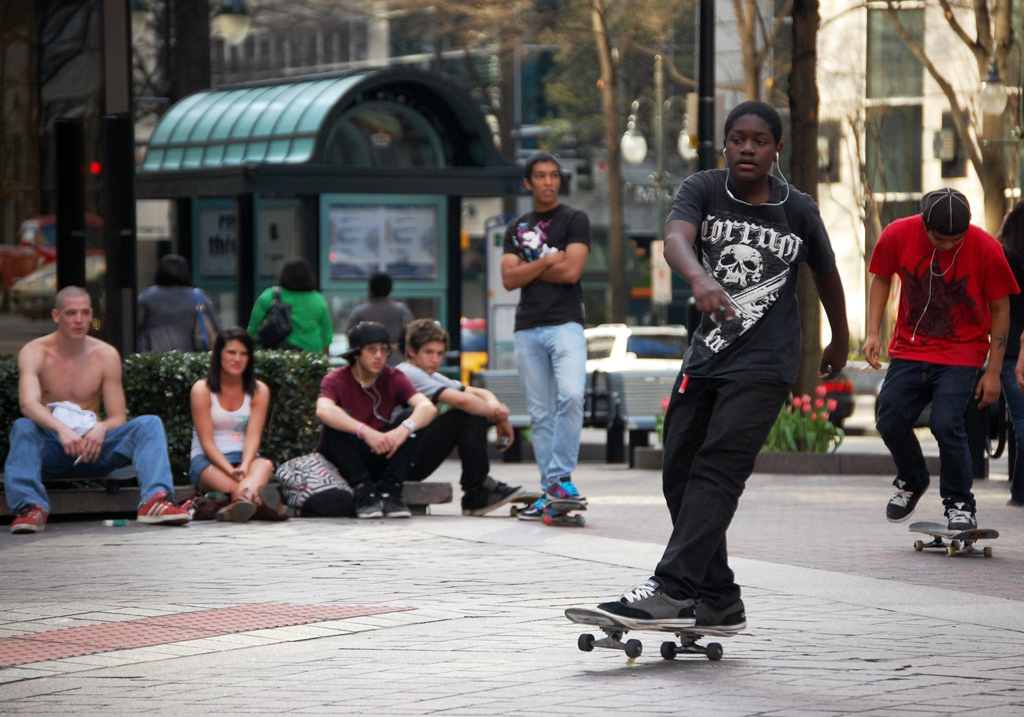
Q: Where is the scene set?
A: Outside on the sidewalk.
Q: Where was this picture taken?
A: On the street.